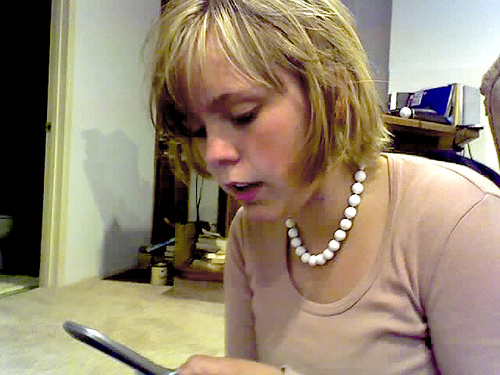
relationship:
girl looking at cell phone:
[135, 0, 500, 374] [62, 319, 172, 374]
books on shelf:
[190, 225, 229, 266] [179, 260, 227, 285]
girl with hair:
[129, 1, 499, 374] [148, 3, 392, 154]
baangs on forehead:
[140, 24, 292, 104] [177, 28, 253, 106]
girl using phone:
[135, 0, 500, 374] [61, 315, 178, 374]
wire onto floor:
[193, 167, 199, 246] [2, 264, 226, 374]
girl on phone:
[129, 1, 499, 374] [52, 313, 184, 374]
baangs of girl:
[140, 0, 324, 104] [135, 0, 500, 374]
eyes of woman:
[176, 96, 264, 138] [136, 16, 499, 368]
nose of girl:
[203, 123, 243, 170] [135, 0, 500, 374]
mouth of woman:
[218, 175, 272, 206] [136, 16, 499, 368]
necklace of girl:
[283, 162, 367, 266] [135, 0, 500, 374]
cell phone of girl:
[61, 317, 181, 374] [135, 0, 500, 374]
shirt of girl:
[217, 146, 499, 373] [135, 0, 500, 374]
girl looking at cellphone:
[135, 0, 500, 374] [59, 316, 178, 373]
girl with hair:
[135, 0, 500, 374] [148, 2, 391, 189]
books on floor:
[144, 222, 227, 273] [5, 273, 230, 368]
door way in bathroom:
[0, 1, 72, 294] [8, 13, 48, 289]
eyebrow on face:
[194, 73, 278, 112] [135, 49, 347, 251]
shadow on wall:
[72, 121, 152, 281] [60, 0, 165, 291]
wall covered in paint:
[58, 0, 497, 285] [331, 0, 494, 174]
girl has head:
[135, 0, 500, 374] [141, 4, 453, 203]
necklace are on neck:
[283, 162, 367, 266] [294, 149, 355, 243]